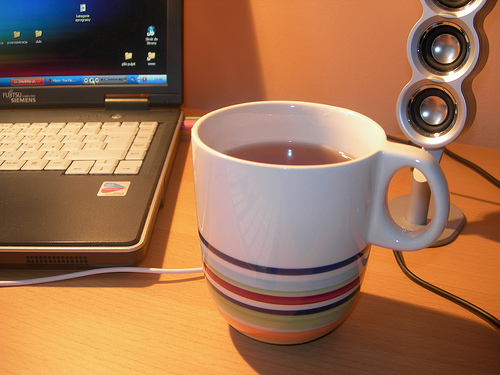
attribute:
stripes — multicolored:
[198, 232, 373, 344]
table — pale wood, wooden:
[1, 105, 498, 373]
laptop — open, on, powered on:
[0, 0, 184, 265]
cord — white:
[1, 266, 204, 288]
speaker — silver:
[397, 0, 487, 149]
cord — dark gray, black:
[394, 250, 500, 331]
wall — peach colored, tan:
[184, 0, 499, 145]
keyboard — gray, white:
[3, 106, 181, 244]